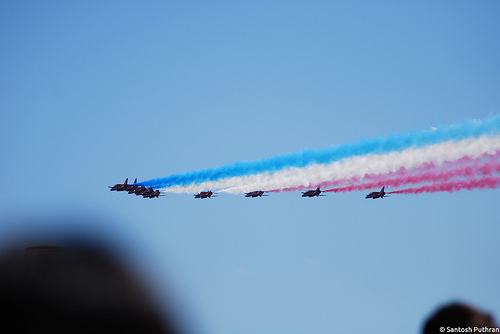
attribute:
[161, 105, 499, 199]
smoke — streams, colorful, blue, colored, trail, white, red, trails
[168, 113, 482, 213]
clouds — white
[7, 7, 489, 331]
sky — blue, bright blue, cloudless, big patch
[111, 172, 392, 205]
jets — in formation, close together, black, several, flying, flying fast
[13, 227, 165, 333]
head — someones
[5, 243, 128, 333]
person — blurry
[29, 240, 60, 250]
tower — some kind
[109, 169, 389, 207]
airplanes — flying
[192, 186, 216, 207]
jet — large, flying, dark colored, gray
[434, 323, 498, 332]
texts — white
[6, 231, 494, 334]
people — watching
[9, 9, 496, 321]
day — daytime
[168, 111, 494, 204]
trails — smoke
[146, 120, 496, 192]
colors — american flag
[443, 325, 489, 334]
name — photographer